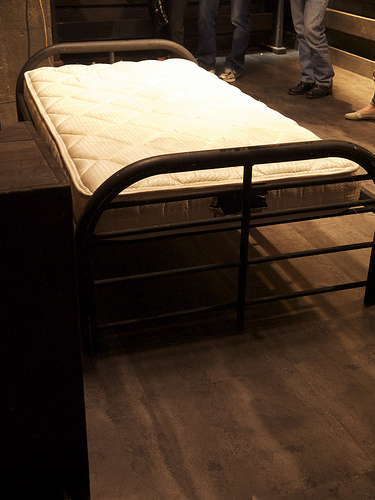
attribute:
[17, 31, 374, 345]
frame — metal, small, grey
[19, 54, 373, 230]
mattress — white, single size, quilted, naked, uncovered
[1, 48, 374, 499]
floor — light brown, tile, dirty, gray, cement, concrete, scuffed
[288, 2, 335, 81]
jeans — men's, blue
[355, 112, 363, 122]
slip — beige, small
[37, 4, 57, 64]
cord — yellow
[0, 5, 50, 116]
wall — concrete block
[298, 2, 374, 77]
slats — wooden, horizontal, wood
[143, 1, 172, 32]
purse — black, small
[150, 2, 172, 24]
decorations — metal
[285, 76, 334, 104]
shoes — black, mens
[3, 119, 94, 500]
chest — wooden, dark, brown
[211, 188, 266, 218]
tag — old, tattered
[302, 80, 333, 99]
shoe — black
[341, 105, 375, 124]
foot — taupe